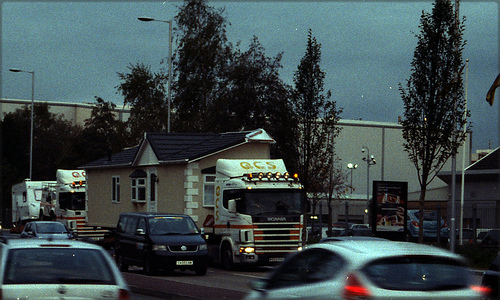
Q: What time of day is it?
A: Day time.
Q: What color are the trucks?
A: White.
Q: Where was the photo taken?
A: On a street.